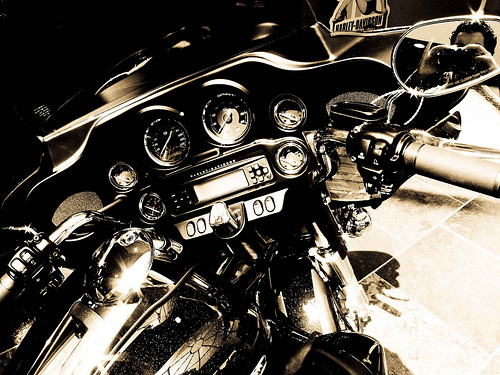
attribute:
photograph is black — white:
[1, 1, 499, 374]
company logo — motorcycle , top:
[330, 12, 384, 34]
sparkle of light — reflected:
[470, 4, 485, 25]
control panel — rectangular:
[114, 79, 313, 226]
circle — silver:
[201, 97, 254, 144]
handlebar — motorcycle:
[338, 125, 495, 196]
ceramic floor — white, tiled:
[361, 177, 499, 375]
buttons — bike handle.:
[247, 162, 266, 183]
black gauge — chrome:
[264, 93, 307, 135]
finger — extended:
[457, 39, 482, 55]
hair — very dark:
[442, 8, 491, 33]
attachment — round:
[63, 238, 206, 340]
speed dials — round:
[133, 116, 355, 163]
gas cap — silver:
[63, 255, 167, 323]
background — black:
[4, 0, 124, 72]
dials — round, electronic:
[91, 88, 358, 231]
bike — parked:
[58, 68, 447, 369]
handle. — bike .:
[54, 78, 465, 219]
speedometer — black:
[140, 118, 192, 160]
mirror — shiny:
[369, 10, 478, 114]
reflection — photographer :
[422, 33, 478, 51]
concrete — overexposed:
[400, 211, 480, 326]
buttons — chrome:
[160, 199, 286, 238]